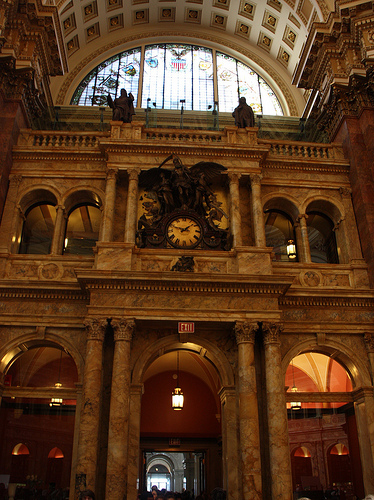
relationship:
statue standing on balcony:
[106, 87, 138, 125] [10, 121, 347, 170]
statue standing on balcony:
[232, 97, 257, 129] [10, 121, 347, 170]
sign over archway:
[177, 319, 196, 334] [128, 331, 241, 500]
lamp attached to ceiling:
[168, 384, 182, 411] [141, 349, 223, 407]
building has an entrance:
[2, 2, 374, 497] [74, 269, 294, 500]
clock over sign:
[165, 215, 204, 251] [177, 319, 196, 334]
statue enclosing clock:
[134, 154, 234, 252] [165, 215, 204, 251]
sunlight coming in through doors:
[148, 478, 168, 489] [143, 451, 191, 494]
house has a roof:
[2, 2, 373, 499] [3, 2, 372, 87]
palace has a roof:
[2, 2, 372, 500] [3, 2, 372, 87]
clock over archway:
[165, 215, 204, 251] [128, 331, 241, 500]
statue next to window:
[106, 87, 138, 125] [53, 22, 308, 122]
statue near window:
[106, 87, 138, 125] [53, 22, 308, 122]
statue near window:
[232, 97, 257, 129] [53, 22, 308, 122]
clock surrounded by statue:
[165, 215, 204, 251] [134, 154, 234, 252]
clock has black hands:
[165, 215, 204, 251] [171, 222, 194, 235]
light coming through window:
[131, 47, 246, 110] [53, 22, 308, 122]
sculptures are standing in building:
[102, 86, 257, 132] [2, 2, 374, 497]